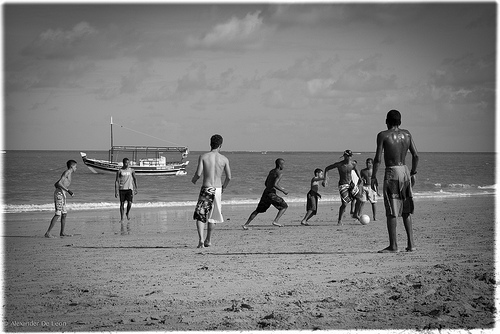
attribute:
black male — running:
[359, 98, 446, 238]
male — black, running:
[240, 155, 291, 229]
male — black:
[331, 143, 360, 165]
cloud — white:
[17, 15, 148, 60]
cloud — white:
[185, 6, 278, 51]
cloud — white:
[261, 2, 433, 32]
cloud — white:
[263, 45, 496, 122]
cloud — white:
[7, 58, 259, 108]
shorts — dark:
[255, 185, 287, 212]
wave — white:
[7, 165, 497, 207]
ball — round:
[353, 212, 375, 224]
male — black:
[240, 147, 295, 234]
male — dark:
[371, 101, 422, 252]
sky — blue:
[78, 12, 497, 123]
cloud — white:
[190, 15, 277, 52]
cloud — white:
[282, 52, 344, 77]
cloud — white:
[407, 70, 477, 120]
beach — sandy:
[4, 196, 495, 328]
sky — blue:
[7, 5, 494, 154]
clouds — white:
[34, 25, 117, 58]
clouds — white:
[175, 73, 221, 100]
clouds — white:
[290, 73, 336, 104]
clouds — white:
[199, 14, 267, 49]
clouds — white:
[410, 69, 473, 103]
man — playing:
[188, 124, 238, 253]